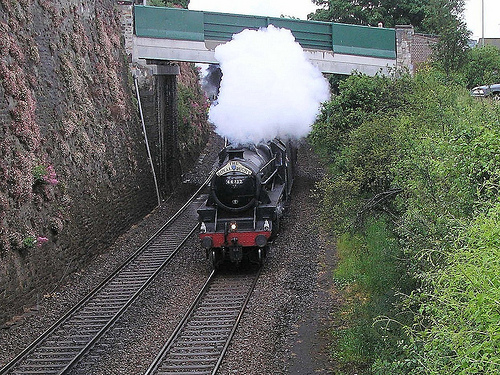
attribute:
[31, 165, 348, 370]
track — iron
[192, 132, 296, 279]
engine — black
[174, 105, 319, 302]
train — old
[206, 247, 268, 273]
wheels — black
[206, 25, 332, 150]
steam — white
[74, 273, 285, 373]
tracks — empty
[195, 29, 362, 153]
steam — opaque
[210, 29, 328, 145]
smoke cloud — big, white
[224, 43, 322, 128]
smoke — big, white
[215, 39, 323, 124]
cloud — white, big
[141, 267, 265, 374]
track — dark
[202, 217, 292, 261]
bumper — red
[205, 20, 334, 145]
cloud — white, big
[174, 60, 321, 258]
steam engine — black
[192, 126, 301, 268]
train — black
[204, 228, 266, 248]
bumper — red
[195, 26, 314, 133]
cloud — big, white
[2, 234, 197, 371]
track — dark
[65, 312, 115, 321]
tie — cross tie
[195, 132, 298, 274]
steam engine — old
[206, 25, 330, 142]
smoke — big, white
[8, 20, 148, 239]
rock wall — large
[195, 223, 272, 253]
bumper — red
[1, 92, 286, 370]
rails — iron